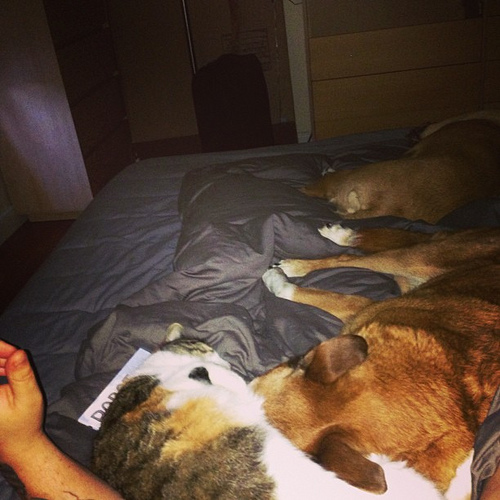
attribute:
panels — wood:
[26, 7, 141, 179]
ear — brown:
[299, 334, 372, 382]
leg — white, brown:
[273, 244, 420, 288]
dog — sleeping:
[319, 105, 499, 252]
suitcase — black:
[166, 50, 268, 150]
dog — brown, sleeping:
[179, 235, 499, 495]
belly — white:
[236, 402, 324, 496]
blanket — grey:
[73, 147, 447, 388]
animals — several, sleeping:
[91, 106, 498, 497]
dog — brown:
[237, 220, 499, 490]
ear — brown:
[293, 332, 369, 384]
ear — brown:
[313, 432, 386, 492]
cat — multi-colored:
[89, 320, 401, 498]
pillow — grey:
[37, 291, 362, 449]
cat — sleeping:
[64, 278, 391, 498]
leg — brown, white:
[313, 217, 413, 249]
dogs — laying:
[243, 107, 498, 491]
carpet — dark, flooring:
[17, 229, 49, 250]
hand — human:
[0, 327, 62, 482]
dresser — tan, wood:
[6, 0, 142, 224]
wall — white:
[107, 50, 174, 97]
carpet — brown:
[3, 219, 72, 310]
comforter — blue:
[66, 135, 472, 499]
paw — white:
[317, 222, 357, 248]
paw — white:
[273, 254, 306, 277]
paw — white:
[258, 269, 300, 299]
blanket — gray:
[0, 146, 499, 498]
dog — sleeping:
[286, 326, 473, 463]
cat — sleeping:
[118, 321, 270, 487]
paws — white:
[261, 214, 369, 314]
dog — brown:
[173, 113, 430, 495]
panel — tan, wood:
[304, 5, 499, 48]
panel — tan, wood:
[306, 21, 499, 79]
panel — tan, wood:
[304, 65, 499, 144]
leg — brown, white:
[264, 259, 371, 333]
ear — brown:
[305, 430, 387, 497]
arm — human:
[5, 432, 115, 497]